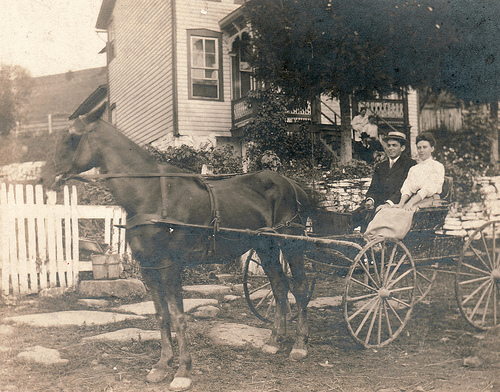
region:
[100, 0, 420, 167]
two storied wooden house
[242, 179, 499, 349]
wooden wheeled buggy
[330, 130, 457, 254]
couple dressed to go for a buggy ride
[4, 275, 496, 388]
dirt yard with some large flat rocks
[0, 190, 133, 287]
picket fence with missing slats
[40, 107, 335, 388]
horse hitched to buggy carrying a couple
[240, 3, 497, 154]
large tree in front yard of house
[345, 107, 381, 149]
two people sitting on the front steps of the house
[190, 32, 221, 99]
open window of home with curtain visible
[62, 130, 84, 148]
blinders over horses eyes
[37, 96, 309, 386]
Horse drawing a carriage.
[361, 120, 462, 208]
A couple riding in the buggy.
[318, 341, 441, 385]
Not a paved road in sight.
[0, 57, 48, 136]
Tree in on the hill.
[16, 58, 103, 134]
Hill in the background.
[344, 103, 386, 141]
Two people sitting on the step.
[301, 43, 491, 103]
Lush green trees in the front yard.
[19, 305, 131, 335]
Part of the sidewalk.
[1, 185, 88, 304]
A white picket fence.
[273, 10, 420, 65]
a tree bush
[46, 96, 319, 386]
a horse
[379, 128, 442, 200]
two people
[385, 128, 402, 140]
man wearing a hat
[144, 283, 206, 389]
the horses leg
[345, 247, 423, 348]
front tire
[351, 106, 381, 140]
people standing on the stairs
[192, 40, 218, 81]
a window on the house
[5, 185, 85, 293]
a white fence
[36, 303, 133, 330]
rocks on the ground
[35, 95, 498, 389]
A horse and carriage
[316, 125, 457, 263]
People sitting in a carriage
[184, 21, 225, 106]
A window on a house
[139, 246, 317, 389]
Four legs of a horse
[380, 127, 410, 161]
Hat on man's head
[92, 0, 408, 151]
A house in the background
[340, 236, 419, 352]
A large round wheel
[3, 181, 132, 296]
A white picket fence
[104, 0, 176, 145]
The side of a house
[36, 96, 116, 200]
Head of a horse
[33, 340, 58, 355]
rock in the grass.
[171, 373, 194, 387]
hoof of the horse.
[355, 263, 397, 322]
wheel below the cart.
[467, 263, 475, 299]
spokes of the wheel.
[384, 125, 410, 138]
hat on man's head.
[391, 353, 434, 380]
dirt on the ground.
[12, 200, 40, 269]
white fence near house.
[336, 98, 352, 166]
trunk of the tree.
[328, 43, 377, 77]
leaves on the tree.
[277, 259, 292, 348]
leg of the horse.